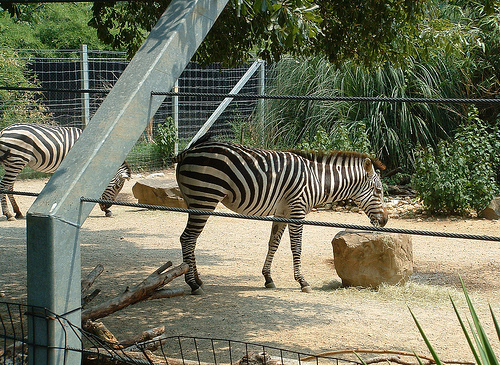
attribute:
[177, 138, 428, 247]
zebra — eating, smelling, sniffing, standing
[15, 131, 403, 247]
zebras — pair, fenced, standing, eating, white, black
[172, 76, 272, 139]
fence — tall, steel, bend, chain, silver, linked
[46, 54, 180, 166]
boulder — large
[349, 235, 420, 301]
boulder — large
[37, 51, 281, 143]
enclosure — steel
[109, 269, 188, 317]
wood — dead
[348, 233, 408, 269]
rock — large, brown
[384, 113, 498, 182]
vegetation — greenery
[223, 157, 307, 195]
stripes — black, white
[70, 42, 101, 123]
post — metal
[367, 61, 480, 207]
bushes — green, small, leafy, large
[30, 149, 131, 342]
beam — metal, blue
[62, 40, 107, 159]
pole — metal, gray, angled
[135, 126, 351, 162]
grass — green